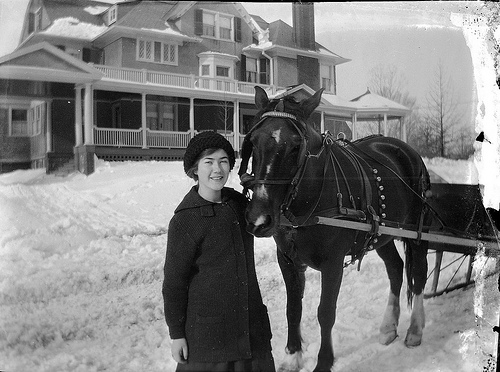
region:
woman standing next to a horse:
[162, 134, 278, 369]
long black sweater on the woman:
[165, 186, 270, 361]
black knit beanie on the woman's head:
[182, 131, 234, 170]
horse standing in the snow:
[241, 85, 433, 363]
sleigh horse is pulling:
[311, 183, 497, 335]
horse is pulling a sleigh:
[238, 85, 427, 370]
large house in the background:
[0, 1, 405, 177]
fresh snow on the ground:
[5, 155, 498, 370]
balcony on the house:
[86, 65, 280, 98]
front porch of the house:
[91, 85, 246, 152]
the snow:
[17, 204, 156, 337]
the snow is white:
[17, 215, 129, 326]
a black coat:
[175, 223, 255, 335]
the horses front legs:
[283, 295, 344, 365]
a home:
[30, 6, 245, 136]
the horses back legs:
[378, 263, 427, 350]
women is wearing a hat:
[193, 133, 208, 148]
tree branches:
[424, 88, 464, 152]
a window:
[157, 39, 179, 64]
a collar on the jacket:
[182, 190, 201, 208]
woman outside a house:
[162, 129, 274, 369]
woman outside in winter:
[162, 129, 277, 369]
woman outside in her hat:
[162, 132, 273, 370]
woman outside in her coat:
[165, 129, 271, 369]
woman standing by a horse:
[162, 131, 274, 370]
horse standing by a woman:
[240, 84, 434, 370]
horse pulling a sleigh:
[243, 84, 498, 370]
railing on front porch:
[95, 124, 261, 149]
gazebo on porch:
[349, 89, 409, 144]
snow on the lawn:
[1, 157, 200, 368]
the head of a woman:
[176, 127, 239, 192]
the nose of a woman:
[211, 158, 222, 175]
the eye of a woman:
[216, 156, 230, 165]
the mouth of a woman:
[206, 172, 224, 184]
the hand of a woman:
[168, 333, 193, 369]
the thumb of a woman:
[181, 341, 192, 361]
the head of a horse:
[232, 75, 332, 241]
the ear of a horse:
[295, 83, 332, 119]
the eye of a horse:
[287, 139, 305, 159]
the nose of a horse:
[240, 202, 280, 232]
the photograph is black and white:
[1, 1, 498, 368]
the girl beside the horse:
[161, 126, 291, 363]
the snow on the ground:
[26, 240, 141, 368]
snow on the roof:
[51, 18, 89, 35]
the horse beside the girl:
[223, 67, 456, 338]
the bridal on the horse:
[231, 118, 391, 224]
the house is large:
[4, 10, 345, 152]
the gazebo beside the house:
[344, 85, 411, 140]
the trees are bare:
[379, 65, 460, 145]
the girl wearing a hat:
[172, 127, 227, 203]